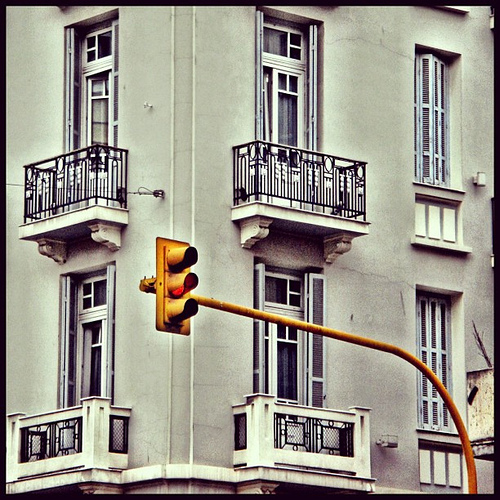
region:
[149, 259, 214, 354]
The traffic light is on the yellow light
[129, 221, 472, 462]
Traffic light is on big yellow curved pole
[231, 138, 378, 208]
Black metal balcony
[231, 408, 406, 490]
White framed balcony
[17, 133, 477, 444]
Large gray building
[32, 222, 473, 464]
Many windows on building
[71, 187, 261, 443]
Corner of building near traffic light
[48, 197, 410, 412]
Traffic light is near building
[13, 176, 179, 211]
Wire attached to building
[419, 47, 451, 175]
Shutters closed on window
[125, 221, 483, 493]
the traffic light is yellow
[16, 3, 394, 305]
the building has balconies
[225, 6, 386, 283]
the balcony has a black railing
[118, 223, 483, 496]
the traffic light pole is yellow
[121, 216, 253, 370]
the middle light is lit on the traffic light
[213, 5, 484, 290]
the building has windows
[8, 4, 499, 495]
the building is light colored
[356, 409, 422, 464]
the building has a light on it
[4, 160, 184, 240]
a power line is attached to the building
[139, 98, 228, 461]
the building has cracks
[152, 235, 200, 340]
a yellow traffic light set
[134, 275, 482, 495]
a yellow traffic light pole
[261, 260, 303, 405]
a window on a building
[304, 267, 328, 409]
a shutter for a window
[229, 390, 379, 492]
the balcony for a window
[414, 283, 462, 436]
a set of closed shutters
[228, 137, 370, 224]
a black metal railing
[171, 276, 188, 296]
a red traffic light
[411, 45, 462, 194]
a set of closed shutters on the building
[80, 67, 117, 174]
an open window on the building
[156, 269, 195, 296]
Red traffic indicator light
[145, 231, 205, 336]
Yellow traffic indicator light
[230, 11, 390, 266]
Grey window on building side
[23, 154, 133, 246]
Grey balcony protruding from building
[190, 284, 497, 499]
Yellow pole for holding up light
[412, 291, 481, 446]
S amll window with no balcony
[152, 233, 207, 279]
Top of yellow traffic light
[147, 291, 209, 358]
Bottom of yellow traffic light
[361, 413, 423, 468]
Emergency lights for building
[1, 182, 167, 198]
A power line hanging overhead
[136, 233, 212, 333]
Stop light over the road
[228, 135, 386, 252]
Balcony on second floor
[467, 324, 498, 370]
Tree branch on patio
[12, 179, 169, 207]
Electric wire attached to building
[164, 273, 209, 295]
Yellow yield light on pole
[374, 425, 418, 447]
Light fixture on side of building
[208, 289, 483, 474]
Bent pole holding stop light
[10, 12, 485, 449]
apartment building with two floors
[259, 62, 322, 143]
Patio door over balcony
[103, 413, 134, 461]
Fenced in part of patio